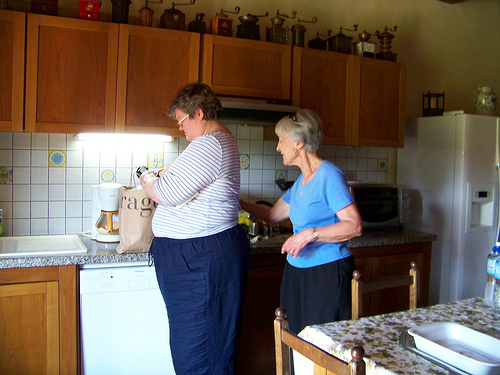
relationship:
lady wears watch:
[243, 114, 364, 330] [311, 226, 320, 244]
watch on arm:
[311, 226, 320, 244] [301, 170, 372, 248]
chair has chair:
[268, 304, 376, 374] [271, 307, 366, 374]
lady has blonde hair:
[243, 114, 364, 330] [270, 105, 327, 151]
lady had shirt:
[243, 114, 364, 330] [279, 162, 364, 266]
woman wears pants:
[149, 85, 263, 375] [150, 226, 249, 375]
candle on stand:
[97, 184, 120, 210] [103, 209, 123, 237]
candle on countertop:
[97, 184, 120, 210] [82, 225, 165, 263]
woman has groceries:
[149, 85, 263, 375] [117, 178, 161, 258]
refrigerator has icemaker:
[399, 111, 500, 299] [470, 181, 496, 231]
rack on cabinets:
[36, 0, 400, 56] [7, 12, 406, 150]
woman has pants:
[149, 85, 263, 375] [150, 226, 249, 375]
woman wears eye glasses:
[149, 85, 263, 375] [173, 113, 190, 124]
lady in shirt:
[243, 114, 364, 330] [279, 162, 364, 266]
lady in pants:
[243, 114, 364, 330] [284, 257, 357, 330]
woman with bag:
[149, 85, 263, 375] [117, 178, 161, 258]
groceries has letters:
[117, 178, 161, 258] [114, 197, 159, 216]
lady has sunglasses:
[243, 114, 364, 330] [290, 109, 301, 130]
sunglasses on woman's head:
[290, 109, 301, 130] [270, 105, 327, 151]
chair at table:
[268, 304, 376, 374] [310, 297, 499, 375]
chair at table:
[347, 257, 428, 315] [310, 297, 499, 375]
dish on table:
[408, 318, 499, 375] [310, 297, 499, 375]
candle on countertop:
[97, 184, 124, 212] [82, 225, 165, 263]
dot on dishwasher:
[110, 275, 115, 281] [84, 267, 181, 375]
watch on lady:
[311, 226, 320, 244] [243, 114, 364, 330]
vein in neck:
[300, 148, 309, 177] [298, 153, 325, 171]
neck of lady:
[298, 153, 325, 171] [243, 114, 364, 330]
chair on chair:
[271, 307, 366, 374] [268, 304, 376, 374]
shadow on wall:
[405, 18, 462, 114] [402, 6, 499, 109]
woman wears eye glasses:
[149, 85, 263, 375] [176, 114, 190, 124]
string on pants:
[149, 245, 158, 267] [150, 226, 249, 375]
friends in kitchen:
[151, 82, 365, 375] [3, 6, 498, 372]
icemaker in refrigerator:
[470, 181, 496, 231] [399, 111, 500, 299]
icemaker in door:
[470, 181, 496, 231] [464, 123, 494, 299]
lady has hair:
[243, 114, 364, 330] [270, 105, 327, 151]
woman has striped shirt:
[149, 85, 263, 375] [136, 133, 242, 238]